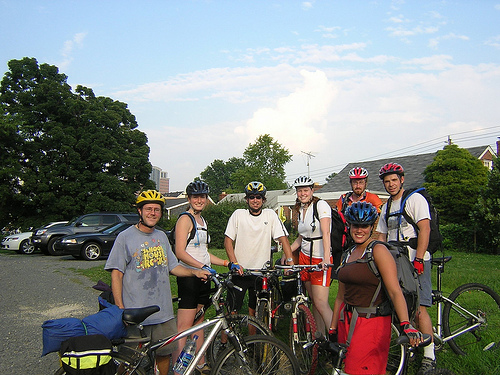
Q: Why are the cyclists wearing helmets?
A: Safety.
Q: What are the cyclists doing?
A: Posing for a picture.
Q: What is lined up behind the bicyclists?
A: Cars.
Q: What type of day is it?
A: Clear.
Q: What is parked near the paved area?
A: Cars.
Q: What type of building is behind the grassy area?
A: A house.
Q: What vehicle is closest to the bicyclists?
A: The black car.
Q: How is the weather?
A: Sunny with scattered clouds.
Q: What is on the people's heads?
A: Helmets.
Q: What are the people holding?
A: Bicycles.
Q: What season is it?
A: Summer.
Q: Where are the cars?
A: Next to the tree.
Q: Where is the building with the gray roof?
A: Behind the parking lot.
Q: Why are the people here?
A: To ride bikes together.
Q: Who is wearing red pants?
A: The woman in the blue helmet and brown shirt.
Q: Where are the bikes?
A: On the grass.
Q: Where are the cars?
A: Parking lot.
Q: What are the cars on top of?
A: Parking lot.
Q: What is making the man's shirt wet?
A: Sweat.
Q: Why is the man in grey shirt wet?
A: He is sweating.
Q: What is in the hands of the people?
A: Bikes.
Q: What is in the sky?
A: Clouds.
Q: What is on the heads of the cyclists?
A: Helmets.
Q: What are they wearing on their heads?
A: Helmets.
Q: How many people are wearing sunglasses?
A: One.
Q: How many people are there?
A: Seven.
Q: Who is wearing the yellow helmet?
A: The man on the left.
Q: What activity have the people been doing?
A: Biking.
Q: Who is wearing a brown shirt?
A: The woman in front.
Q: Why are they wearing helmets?
A: They are biking.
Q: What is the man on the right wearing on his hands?
A: Gloves.